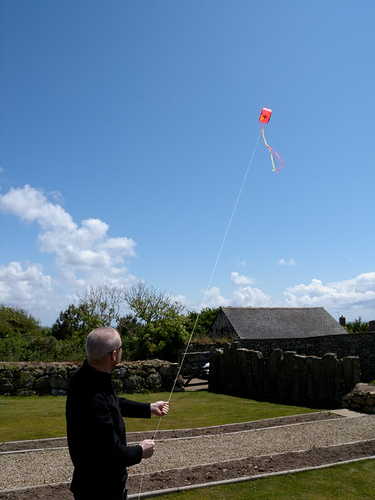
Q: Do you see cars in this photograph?
A: No, there are no cars.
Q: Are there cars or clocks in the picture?
A: No, there are no cars or clocks.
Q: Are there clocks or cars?
A: No, there are no cars or clocks.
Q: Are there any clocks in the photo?
A: No, there are no clocks.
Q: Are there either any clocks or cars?
A: No, there are no clocks or cars.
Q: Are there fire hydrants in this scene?
A: No, there are no fire hydrants.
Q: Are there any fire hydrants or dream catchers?
A: No, there are no fire hydrants or dream catchers.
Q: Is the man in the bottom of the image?
A: Yes, the man is in the bottom of the image.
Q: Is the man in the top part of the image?
A: No, the man is in the bottom of the image.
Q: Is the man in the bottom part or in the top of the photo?
A: The man is in the bottom of the image.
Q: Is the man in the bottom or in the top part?
A: The man is in the bottom of the image.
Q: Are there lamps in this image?
A: No, there are no lamps.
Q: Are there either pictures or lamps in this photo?
A: No, there are no lamps or pictures.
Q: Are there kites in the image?
A: Yes, there is a kite.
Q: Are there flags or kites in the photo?
A: Yes, there is a kite.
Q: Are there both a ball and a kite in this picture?
A: No, there is a kite but no balls.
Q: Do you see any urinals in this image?
A: No, there are no urinals.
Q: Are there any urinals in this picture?
A: No, there are no urinals.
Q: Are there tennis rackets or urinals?
A: No, there are no urinals or tennis rackets.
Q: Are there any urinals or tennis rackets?
A: No, there are no urinals or tennis rackets.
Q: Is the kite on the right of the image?
A: Yes, the kite is on the right of the image.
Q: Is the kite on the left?
A: No, the kite is on the right of the image.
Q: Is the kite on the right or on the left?
A: The kite is on the right of the image.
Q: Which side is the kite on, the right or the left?
A: The kite is on the right of the image.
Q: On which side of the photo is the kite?
A: The kite is on the right of the image.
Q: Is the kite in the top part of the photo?
A: Yes, the kite is in the top of the image.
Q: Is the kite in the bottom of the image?
A: No, the kite is in the top of the image.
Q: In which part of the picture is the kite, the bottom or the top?
A: The kite is in the top of the image.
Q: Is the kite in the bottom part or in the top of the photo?
A: The kite is in the top of the image.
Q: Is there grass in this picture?
A: Yes, there is grass.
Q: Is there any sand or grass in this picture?
A: Yes, there is grass.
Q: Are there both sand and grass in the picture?
A: No, there is grass but no sand.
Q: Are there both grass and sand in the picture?
A: No, there is grass but no sand.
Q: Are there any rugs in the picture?
A: No, there are no rugs.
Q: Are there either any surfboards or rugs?
A: No, there are no rugs or surfboards.